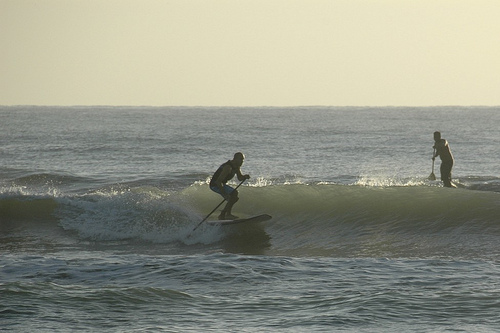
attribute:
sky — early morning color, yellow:
[0, 2, 500, 107]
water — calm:
[293, 107, 363, 144]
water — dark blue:
[261, 101, 358, 183]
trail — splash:
[65, 185, 223, 247]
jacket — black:
[204, 159, 249, 183]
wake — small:
[60, 192, 225, 242]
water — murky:
[0, 107, 498, 330]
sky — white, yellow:
[253, 20, 470, 100]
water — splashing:
[272, 172, 437, 237]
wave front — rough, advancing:
[38, 186, 495, 283]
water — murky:
[287, 205, 400, 240]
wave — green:
[67, 102, 443, 237]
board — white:
[207, 211, 275, 227]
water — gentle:
[5, 239, 493, 326]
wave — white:
[61, 165, 172, 256]